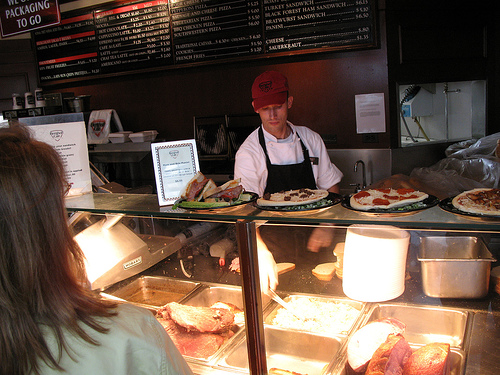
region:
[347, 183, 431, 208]
pizza on top of glass counter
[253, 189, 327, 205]
pizza on top of glass counter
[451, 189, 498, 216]
pizza on top of glass counter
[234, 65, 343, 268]
man wearing red cap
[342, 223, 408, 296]
stack of white plates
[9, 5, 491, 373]
man selling in a store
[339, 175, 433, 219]
uncooked pizza over a glass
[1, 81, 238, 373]
woman buying in a store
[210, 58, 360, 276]
man wearing black apron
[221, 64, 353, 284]
man wears white shirt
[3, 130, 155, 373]
woman has brown hair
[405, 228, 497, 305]
a rectangle container of silver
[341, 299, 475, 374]
pieces of ham in a container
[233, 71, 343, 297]
employee in a restaurant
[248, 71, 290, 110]
a man's employee cap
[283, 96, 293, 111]
a man's left ear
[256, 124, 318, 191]
a man's work apron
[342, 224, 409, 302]
stack of white styrofoam plates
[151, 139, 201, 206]
a menu with prices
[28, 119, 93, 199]
list in a restaurant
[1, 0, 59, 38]
to go orders sign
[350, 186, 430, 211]
a pepperoni pizza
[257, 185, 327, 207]
sausage and cheese pizza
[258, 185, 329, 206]
gourmet pizza ready for pickup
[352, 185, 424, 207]
gourmet pizza ready for pickup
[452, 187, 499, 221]
gourmet pizza ready for pickup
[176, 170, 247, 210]
gourmet dish ready for pickup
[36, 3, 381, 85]
black and red menu above man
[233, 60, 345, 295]
line cook preparing a dish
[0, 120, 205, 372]
long haired lady waiting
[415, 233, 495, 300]
silver bin for buffet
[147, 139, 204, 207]
daily special sign is framed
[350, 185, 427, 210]
pizza with large pepperooni slices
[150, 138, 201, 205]
white paper standing up on the counter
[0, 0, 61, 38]
sign says Packagin to go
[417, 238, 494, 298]
square silver metal tub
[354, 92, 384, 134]
white paper on the wall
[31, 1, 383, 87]
large black menu on the back wall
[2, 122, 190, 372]
woman ordering food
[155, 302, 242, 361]
container of roast beef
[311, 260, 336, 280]
piece of bread on the counter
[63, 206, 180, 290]
silver metal meat slicer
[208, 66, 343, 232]
a person wearing a white shirt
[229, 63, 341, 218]
a person wearing a shirt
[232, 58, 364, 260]
a person wearing an apron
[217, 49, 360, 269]
a person wearing a black apron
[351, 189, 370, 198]
pepperoni on top of pizza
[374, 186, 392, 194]
pepperoni on top of pizza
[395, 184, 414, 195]
pepperoni on top of pizza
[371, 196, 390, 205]
pepperoni on top of pizza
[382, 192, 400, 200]
pepperoni on top of pizza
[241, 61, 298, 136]
Red hat on a guy's head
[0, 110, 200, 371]
Woman has long brown hair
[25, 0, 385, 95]
A menu up on the wall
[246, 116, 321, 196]
An apron is black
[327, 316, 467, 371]
Meat in a silver pan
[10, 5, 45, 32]
"TO GO" written on a sign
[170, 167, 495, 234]
Four plates of food on countertop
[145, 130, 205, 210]
Black writing on white paper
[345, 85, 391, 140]
A white paper posted on the wall